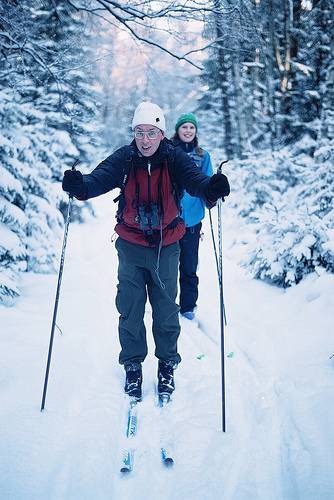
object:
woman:
[168, 113, 214, 320]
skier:
[62, 101, 231, 396]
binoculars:
[134, 202, 159, 229]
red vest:
[114, 161, 186, 247]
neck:
[134, 142, 163, 160]